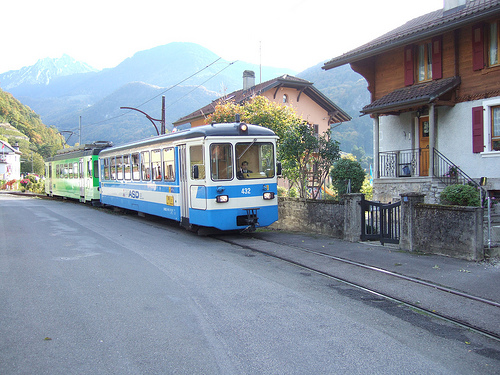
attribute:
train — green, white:
[37, 148, 95, 198]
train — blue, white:
[95, 117, 285, 240]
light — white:
[146, 172, 319, 223]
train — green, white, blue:
[43, 121, 275, 233]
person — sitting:
[235, 159, 253, 179]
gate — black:
[344, 196, 420, 243]